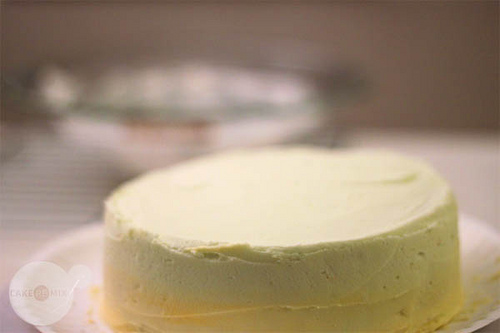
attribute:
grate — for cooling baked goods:
[5, 93, 145, 234]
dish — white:
[2, 203, 497, 331]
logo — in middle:
[2, 257, 141, 319]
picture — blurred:
[32, 29, 366, 150]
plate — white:
[20, 191, 90, 329]